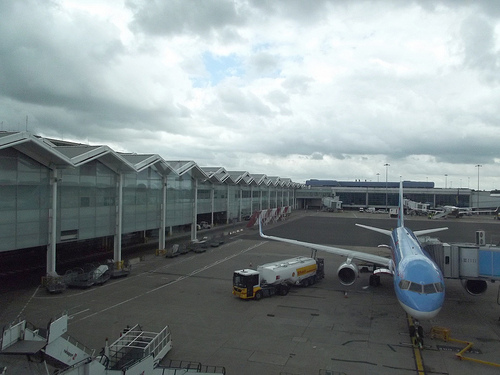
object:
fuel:
[227, 246, 328, 305]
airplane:
[253, 174, 499, 323]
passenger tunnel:
[415, 237, 497, 281]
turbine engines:
[332, 259, 362, 288]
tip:
[249, 208, 274, 240]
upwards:
[253, 210, 269, 243]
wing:
[255, 212, 392, 270]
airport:
[3, 123, 496, 373]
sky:
[2, 1, 499, 149]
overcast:
[3, 0, 498, 140]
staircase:
[9, 300, 222, 374]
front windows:
[420, 283, 435, 293]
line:
[389, 284, 435, 374]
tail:
[391, 174, 407, 228]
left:
[3, 114, 251, 265]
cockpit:
[395, 263, 446, 296]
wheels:
[249, 290, 264, 303]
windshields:
[230, 272, 249, 288]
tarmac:
[22, 200, 498, 355]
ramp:
[421, 234, 500, 281]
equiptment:
[40, 276, 70, 292]